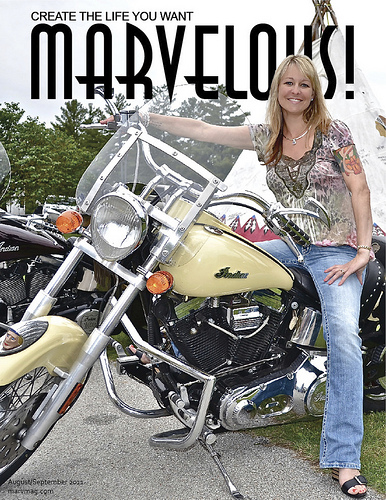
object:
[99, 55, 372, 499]
lady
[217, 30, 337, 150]
open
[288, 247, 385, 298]
seat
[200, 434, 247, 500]
foot rest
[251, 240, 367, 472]
jean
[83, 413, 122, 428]
stain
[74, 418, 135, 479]
concrete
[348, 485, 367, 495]
toes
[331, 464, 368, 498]
sandle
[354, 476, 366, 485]
nail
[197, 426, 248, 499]
stand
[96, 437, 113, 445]
gravel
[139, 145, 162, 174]
reflection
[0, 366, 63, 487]
tire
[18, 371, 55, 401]
spokes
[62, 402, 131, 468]
pavement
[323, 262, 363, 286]
finger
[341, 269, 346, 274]
ring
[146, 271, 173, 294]
light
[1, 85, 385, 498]
bike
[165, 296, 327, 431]
engine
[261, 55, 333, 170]
hair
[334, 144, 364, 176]
tattoo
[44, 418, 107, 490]
asphalt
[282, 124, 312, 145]
necklace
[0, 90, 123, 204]
tree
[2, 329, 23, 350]
head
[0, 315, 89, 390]
fender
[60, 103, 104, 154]
leave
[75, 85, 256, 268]
windshield